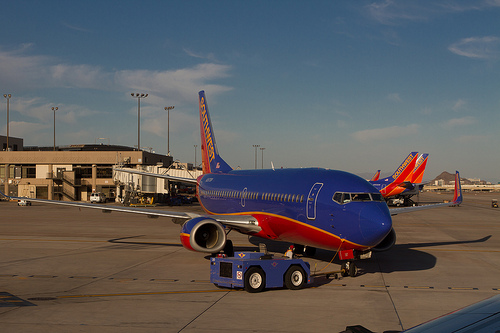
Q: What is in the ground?
A: Plane.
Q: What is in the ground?
A: Plane.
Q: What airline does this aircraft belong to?
A: Southwest Airlines.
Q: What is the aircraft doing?
A: The airplane is parked.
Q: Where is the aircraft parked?
A: The tarmac of the airport.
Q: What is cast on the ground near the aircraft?
A: A shadow is cast on the ground.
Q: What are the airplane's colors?
A: The airplane is blue and red.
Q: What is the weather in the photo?
A: Sunny with little cloud cover.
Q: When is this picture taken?
A: Maybe afternoon.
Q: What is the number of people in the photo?
A: There are zero people.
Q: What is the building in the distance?
A: Part of the airport hub.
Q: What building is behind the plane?
A: Airport.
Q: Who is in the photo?
A: A man.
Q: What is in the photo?
A: A plane.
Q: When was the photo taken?
A: Daytime.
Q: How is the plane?
A: Motionless.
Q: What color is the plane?
A: Blue.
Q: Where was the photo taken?
A: At an airport.